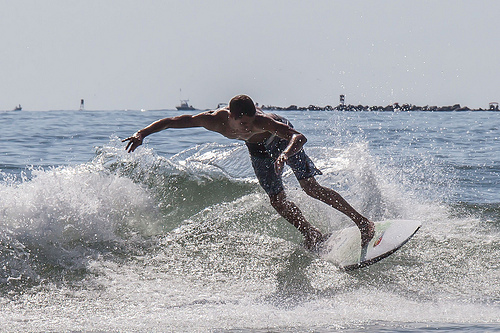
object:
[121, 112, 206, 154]
arm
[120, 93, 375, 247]
surfer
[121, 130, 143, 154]
hand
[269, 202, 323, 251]
leg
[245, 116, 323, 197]
shorts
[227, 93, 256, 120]
hair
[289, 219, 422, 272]
surfboard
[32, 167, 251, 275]
waves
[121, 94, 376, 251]
man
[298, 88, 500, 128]
land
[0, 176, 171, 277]
wave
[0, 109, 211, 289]
ocean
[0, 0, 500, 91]
sky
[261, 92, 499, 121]
island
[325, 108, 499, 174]
water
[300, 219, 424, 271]
board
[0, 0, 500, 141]
background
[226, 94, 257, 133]
head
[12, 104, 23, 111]
boat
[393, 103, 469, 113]
rocks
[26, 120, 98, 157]
ripples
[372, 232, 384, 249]
design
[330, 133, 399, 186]
foam